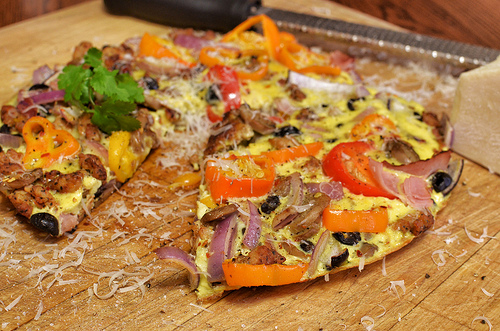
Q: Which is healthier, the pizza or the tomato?
A: The tomato is healthier than the pizza.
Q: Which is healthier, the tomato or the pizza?
A: The tomato is healthier than the pizza.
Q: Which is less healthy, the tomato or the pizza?
A: The pizza is less healthy than the tomato.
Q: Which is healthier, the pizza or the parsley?
A: The parsley is healthier than the pizza.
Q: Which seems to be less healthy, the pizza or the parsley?
A: The pizza is less healthy than the parsley.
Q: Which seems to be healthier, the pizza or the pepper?
A: The pepper is healthier than the pizza.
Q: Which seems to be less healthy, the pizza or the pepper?
A: The pizza is less healthy than the pepper.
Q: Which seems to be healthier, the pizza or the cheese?
A: The cheese is healthier than the pizza.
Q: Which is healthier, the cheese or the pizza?
A: The cheese is healthier than the pizza.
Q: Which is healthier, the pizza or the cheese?
A: The cheese is healthier than the pizza.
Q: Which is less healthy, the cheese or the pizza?
A: The pizza is less healthy than the cheese.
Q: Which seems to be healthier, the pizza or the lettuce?
A: The lettuce is healthier than the pizza.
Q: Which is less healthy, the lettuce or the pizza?
A: The pizza is less healthy than the lettuce.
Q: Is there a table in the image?
A: Yes, there is a table.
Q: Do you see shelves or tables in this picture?
A: Yes, there is a table.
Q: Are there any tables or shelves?
A: Yes, there is a table.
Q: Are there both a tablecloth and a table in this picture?
A: No, there is a table but no tablecloths.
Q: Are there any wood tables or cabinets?
A: Yes, there is a wood table.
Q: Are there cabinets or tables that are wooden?
A: Yes, the table is wooden.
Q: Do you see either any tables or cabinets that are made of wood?
A: Yes, the table is made of wood.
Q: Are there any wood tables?
A: Yes, there is a table that is made of wood.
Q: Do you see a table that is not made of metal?
A: Yes, there is a table that is made of wood.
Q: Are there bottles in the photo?
A: No, there are no bottles.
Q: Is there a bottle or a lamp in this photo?
A: No, there are no bottles or lamps.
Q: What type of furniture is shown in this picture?
A: The furniture is a table.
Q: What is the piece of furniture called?
A: The piece of furniture is a table.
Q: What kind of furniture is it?
A: The piece of furniture is a table.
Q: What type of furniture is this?
A: This is a table.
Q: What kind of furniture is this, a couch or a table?
A: This is a table.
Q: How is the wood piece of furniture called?
A: The piece of furniture is a table.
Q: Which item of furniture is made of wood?
A: The piece of furniture is a table.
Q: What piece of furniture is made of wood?
A: The piece of furniture is a table.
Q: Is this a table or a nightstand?
A: This is a table.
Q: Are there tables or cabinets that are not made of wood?
A: No, there is a table but it is made of wood.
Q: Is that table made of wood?
A: Yes, the table is made of wood.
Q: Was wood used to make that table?
A: Yes, the table is made of wood.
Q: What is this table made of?
A: The table is made of wood.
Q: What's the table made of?
A: The table is made of wood.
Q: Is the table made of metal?
A: No, the table is made of wood.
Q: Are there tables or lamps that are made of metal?
A: No, there is a table but it is made of wood.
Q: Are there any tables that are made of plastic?
A: No, there is a table but it is made of wood.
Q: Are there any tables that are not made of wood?
A: No, there is a table but it is made of wood.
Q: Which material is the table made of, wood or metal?
A: The table is made of wood.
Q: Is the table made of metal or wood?
A: The table is made of wood.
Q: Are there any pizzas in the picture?
A: Yes, there is a pizza.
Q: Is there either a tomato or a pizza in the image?
A: Yes, there is a pizza.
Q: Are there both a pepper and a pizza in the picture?
A: Yes, there are both a pizza and a pepper.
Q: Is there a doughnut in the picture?
A: No, there are no donuts.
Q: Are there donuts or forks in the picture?
A: No, there are no donuts or forks.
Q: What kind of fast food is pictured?
A: The fast food is a pizza.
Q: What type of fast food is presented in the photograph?
A: The fast food is a pizza.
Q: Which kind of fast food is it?
A: The food is a pizza.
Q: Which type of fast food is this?
A: This is a pizza.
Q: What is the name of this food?
A: This is a pizza.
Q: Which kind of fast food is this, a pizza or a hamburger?
A: This is a pizza.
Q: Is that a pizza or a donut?
A: That is a pizza.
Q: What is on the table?
A: The pizza is on the table.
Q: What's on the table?
A: The pizza is on the table.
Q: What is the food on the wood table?
A: The food is a pizza.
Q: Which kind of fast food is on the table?
A: The food is a pizza.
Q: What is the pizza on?
A: The pizza is on the table.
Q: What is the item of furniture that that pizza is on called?
A: The piece of furniture is a table.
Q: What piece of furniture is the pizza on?
A: The pizza is on the table.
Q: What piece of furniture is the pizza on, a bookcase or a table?
A: The pizza is on a table.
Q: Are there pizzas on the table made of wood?
A: Yes, there is a pizza on the table.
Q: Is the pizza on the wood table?
A: Yes, the pizza is on the table.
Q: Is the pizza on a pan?
A: No, the pizza is on the table.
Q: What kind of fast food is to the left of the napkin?
A: The food is a pizza.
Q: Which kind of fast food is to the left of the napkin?
A: The food is a pizza.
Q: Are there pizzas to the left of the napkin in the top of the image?
A: Yes, there is a pizza to the left of the napkin.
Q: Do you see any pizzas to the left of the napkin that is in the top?
A: Yes, there is a pizza to the left of the napkin.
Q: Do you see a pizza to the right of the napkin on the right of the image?
A: No, the pizza is to the left of the napkin.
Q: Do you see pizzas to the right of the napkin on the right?
A: No, the pizza is to the left of the napkin.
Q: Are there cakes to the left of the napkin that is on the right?
A: No, there is a pizza to the left of the napkin.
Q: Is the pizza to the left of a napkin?
A: Yes, the pizza is to the left of a napkin.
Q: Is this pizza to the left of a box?
A: No, the pizza is to the left of a napkin.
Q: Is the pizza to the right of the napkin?
A: No, the pizza is to the left of the napkin.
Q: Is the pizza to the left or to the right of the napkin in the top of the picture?
A: The pizza is to the left of the napkin.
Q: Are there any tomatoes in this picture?
A: Yes, there is a tomato.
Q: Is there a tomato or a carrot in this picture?
A: Yes, there is a tomato.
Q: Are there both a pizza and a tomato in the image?
A: Yes, there are both a tomato and a pizza.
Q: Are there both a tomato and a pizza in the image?
A: Yes, there are both a tomato and a pizza.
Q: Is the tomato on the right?
A: Yes, the tomato is on the right of the image.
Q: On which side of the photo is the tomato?
A: The tomato is on the right of the image.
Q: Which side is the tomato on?
A: The tomato is on the right of the image.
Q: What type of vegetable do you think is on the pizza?
A: The vegetable is a tomato.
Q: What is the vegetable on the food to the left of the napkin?
A: The vegetable is a tomato.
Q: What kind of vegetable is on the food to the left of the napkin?
A: The vegetable is a tomato.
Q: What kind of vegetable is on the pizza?
A: The vegetable is a tomato.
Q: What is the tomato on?
A: The tomato is on the pizza.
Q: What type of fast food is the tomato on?
A: The tomato is on the pizza.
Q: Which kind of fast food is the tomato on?
A: The tomato is on the pizza.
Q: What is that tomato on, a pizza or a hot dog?
A: The tomato is on a pizza.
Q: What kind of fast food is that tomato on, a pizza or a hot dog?
A: The tomato is on a pizza.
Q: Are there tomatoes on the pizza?
A: Yes, there is a tomato on the pizza.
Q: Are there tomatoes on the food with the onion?
A: Yes, there is a tomato on the pizza.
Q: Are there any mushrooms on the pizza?
A: No, there is a tomato on the pizza.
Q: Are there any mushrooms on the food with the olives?
A: No, there is a tomato on the pizza.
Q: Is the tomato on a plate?
A: No, the tomato is on the pizza.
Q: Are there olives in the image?
A: Yes, there are olives.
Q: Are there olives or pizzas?
A: Yes, there are olives.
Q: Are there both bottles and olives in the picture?
A: No, there are olives but no bottles.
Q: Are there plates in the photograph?
A: No, there are no plates.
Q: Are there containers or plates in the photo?
A: No, there are no plates or containers.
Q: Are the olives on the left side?
A: Yes, the olives are on the left of the image.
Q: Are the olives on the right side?
A: No, the olives are on the left of the image.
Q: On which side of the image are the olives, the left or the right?
A: The olives are on the left of the image.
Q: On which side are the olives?
A: The olives are on the left of the image.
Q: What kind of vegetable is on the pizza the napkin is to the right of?
A: The vegetables are olives.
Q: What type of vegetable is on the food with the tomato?
A: The vegetables are olives.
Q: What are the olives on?
A: The olives are on the pizza.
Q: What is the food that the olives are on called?
A: The food is a pizza.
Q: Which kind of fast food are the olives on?
A: The olives are on the pizza.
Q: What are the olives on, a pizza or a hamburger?
A: The olives are on a pizza.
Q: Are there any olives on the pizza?
A: Yes, there are olives on the pizza.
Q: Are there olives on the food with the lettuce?
A: Yes, there are olives on the pizza.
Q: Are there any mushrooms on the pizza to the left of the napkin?
A: No, there are olives on the pizza.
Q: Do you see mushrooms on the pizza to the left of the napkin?
A: No, there are olives on the pizza.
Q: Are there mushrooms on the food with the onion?
A: No, there are olives on the pizza.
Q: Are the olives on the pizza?
A: Yes, the olives are on the pizza.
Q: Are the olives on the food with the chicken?
A: Yes, the olives are on the pizza.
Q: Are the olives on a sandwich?
A: No, the olives are on the pizza.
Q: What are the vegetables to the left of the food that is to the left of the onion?
A: The vegetables are olives.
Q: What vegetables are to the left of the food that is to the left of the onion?
A: The vegetables are olives.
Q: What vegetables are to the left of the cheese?
A: The vegetables are olives.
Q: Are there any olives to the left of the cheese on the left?
A: Yes, there are olives to the left of the cheese.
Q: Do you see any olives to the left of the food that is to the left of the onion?
A: Yes, there are olives to the left of the cheese.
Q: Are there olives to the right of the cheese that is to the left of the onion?
A: No, the olives are to the left of the cheese.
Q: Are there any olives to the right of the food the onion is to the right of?
A: No, the olives are to the left of the cheese.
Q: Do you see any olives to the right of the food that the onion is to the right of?
A: No, the olives are to the left of the cheese.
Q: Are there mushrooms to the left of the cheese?
A: No, there are olives to the left of the cheese.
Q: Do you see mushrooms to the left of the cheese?
A: No, there are olives to the left of the cheese.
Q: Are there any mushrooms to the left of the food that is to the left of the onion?
A: No, there are olives to the left of the cheese.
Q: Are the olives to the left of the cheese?
A: Yes, the olives are to the left of the cheese.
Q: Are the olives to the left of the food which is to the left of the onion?
A: Yes, the olives are to the left of the cheese.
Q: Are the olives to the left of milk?
A: No, the olives are to the left of the cheese.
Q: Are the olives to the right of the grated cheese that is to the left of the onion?
A: No, the olives are to the left of the cheese.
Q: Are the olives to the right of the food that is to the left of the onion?
A: No, the olives are to the left of the cheese.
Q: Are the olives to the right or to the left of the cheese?
A: The olives are to the left of the cheese.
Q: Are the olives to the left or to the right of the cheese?
A: The olives are to the left of the cheese.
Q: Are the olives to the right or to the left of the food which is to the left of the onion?
A: The olives are to the left of the cheese.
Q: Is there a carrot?
A: No, there are no carrots.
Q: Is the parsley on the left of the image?
A: Yes, the parsley is on the left of the image.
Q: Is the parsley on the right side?
A: No, the parsley is on the left of the image.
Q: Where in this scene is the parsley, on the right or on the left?
A: The parsley is on the left of the image.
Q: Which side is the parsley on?
A: The parsley is on the left of the image.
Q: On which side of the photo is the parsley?
A: The parsley is on the left of the image.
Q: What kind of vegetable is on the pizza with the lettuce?
A: The vegetable is parsley.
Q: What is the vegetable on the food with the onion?
A: The vegetable is parsley.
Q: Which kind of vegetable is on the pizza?
A: The vegetable is parsley.